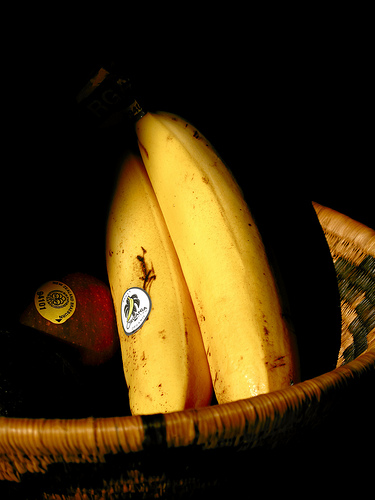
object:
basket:
[0, 197, 375, 498]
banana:
[107, 148, 212, 413]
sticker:
[118, 286, 150, 332]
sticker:
[33, 280, 74, 325]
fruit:
[0, 69, 301, 418]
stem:
[86, 67, 153, 121]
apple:
[19, 272, 114, 370]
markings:
[333, 253, 375, 368]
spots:
[135, 245, 160, 293]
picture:
[122, 292, 140, 330]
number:
[37, 288, 45, 308]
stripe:
[139, 411, 170, 451]